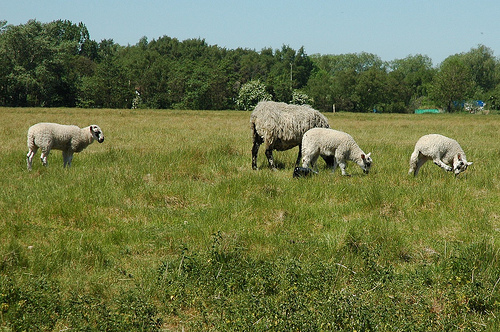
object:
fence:
[410, 100, 445, 114]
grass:
[0, 105, 499, 332]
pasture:
[0, 0, 499, 332]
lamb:
[301, 127, 373, 176]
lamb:
[25, 123, 105, 173]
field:
[0, 106, 499, 331]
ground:
[0, 107, 499, 331]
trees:
[0, 17, 499, 116]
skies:
[0, 0, 499, 60]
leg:
[265, 142, 277, 166]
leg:
[250, 135, 259, 170]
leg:
[406, 149, 420, 174]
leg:
[25, 145, 33, 170]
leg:
[40, 146, 48, 168]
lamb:
[408, 133, 474, 177]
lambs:
[247, 101, 331, 172]